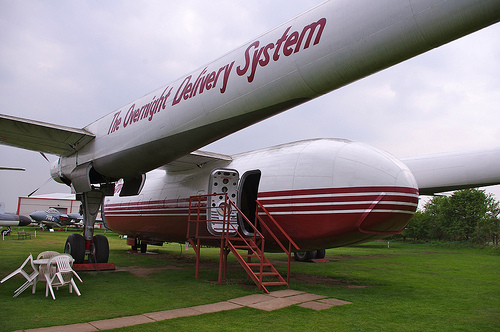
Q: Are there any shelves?
A: No, there are no shelves.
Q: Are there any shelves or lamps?
A: No, there are no shelves or lamps.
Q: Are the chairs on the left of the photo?
A: Yes, the chairs are on the left of the image.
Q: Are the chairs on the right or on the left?
A: The chairs are on the left of the image.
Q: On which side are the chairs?
A: The chairs are on the left of the image.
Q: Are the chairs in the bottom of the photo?
A: Yes, the chairs are in the bottom of the image.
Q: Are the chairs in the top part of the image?
A: No, the chairs are in the bottom of the image.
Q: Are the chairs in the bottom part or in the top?
A: The chairs are in the bottom of the image.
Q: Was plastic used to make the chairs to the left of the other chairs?
A: Yes, the chairs are made of plastic.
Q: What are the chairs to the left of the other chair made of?
A: The chairs are made of plastic.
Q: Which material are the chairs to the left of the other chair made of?
A: The chairs are made of plastic.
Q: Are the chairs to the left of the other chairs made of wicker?
A: No, the chairs are made of plastic.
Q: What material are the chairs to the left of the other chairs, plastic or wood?
A: The chairs are made of plastic.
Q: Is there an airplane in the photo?
A: Yes, there is an airplane.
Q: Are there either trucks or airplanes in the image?
A: Yes, there is an airplane.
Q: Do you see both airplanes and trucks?
A: No, there is an airplane but no trucks.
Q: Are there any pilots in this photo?
A: No, there are no pilots.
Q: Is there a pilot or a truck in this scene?
A: No, there are no pilots or trucks.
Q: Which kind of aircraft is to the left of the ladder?
A: The aircraft is an airplane.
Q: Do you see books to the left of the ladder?
A: No, there is an airplane to the left of the ladder.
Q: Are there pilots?
A: No, there are no pilots.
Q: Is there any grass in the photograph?
A: Yes, there is grass.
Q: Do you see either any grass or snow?
A: Yes, there is grass.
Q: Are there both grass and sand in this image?
A: No, there is grass but no sand.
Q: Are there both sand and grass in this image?
A: No, there is grass but no sand.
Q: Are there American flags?
A: No, there are no American flags.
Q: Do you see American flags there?
A: No, there are no American flags.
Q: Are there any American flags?
A: No, there are no American flags.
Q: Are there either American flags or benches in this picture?
A: No, there are no American flags or benches.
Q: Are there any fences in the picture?
A: No, there are no fences.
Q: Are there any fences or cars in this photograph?
A: No, there are no fences or cars.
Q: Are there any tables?
A: Yes, there is a table.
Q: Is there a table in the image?
A: Yes, there is a table.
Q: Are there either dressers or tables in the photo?
A: Yes, there is a table.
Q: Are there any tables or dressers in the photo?
A: Yes, there is a table.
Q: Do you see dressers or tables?
A: Yes, there is a table.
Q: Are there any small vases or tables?
A: Yes, there is a small table.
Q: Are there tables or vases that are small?
A: Yes, the table is small.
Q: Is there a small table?
A: Yes, there is a small table.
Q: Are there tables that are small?
A: Yes, there is a table that is small.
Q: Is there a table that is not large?
A: Yes, there is a small table.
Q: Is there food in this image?
A: No, there is no food.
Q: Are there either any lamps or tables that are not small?
A: No, there is a table but it is small.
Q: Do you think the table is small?
A: Yes, the table is small.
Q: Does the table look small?
A: Yes, the table is small.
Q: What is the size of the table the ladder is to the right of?
A: The table is small.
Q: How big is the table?
A: The table is small.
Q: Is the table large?
A: No, the table is small.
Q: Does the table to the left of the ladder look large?
A: No, the table is small.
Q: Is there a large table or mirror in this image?
A: No, there is a table but it is small.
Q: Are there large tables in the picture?
A: No, there is a table but it is small.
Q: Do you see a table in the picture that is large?
A: No, there is a table but it is small.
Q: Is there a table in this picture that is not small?
A: No, there is a table but it is small.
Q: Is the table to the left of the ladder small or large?
A: The table is small.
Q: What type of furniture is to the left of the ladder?
A: The piece of furniture is a table.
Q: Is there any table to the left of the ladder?
A: Yes, there is a table to the left of the ladder.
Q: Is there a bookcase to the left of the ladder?
A: No, there is a table to the left of the ladder.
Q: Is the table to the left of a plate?
A: No, the table is to the left of the ladder.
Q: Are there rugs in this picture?
A: No, there are no rugs.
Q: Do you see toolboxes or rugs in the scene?
A: No, there are no rugs or toolboxes.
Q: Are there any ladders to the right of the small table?
A: Yes, there is a ladder to the right of the table.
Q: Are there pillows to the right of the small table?
A: No, there is a ladder to the right of the table.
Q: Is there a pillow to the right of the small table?
A: No, there is a ladder to the right of the table.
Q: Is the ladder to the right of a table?
A: Yes, the ladder is to the right of a table.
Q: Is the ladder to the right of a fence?
A: No, the ladder is to the right of a table.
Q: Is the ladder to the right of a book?
A: No, the ladder is to the right of an airplane.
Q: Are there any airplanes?
A: Yes, there is an airplane.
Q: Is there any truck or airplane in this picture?
A: Yes, there is an airplane.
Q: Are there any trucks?
A: No, there are no trucks.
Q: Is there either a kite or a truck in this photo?
A: No, there are no trucks or kites.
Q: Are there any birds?
A: No, there are no birds.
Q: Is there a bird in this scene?
A: No, there are no birds.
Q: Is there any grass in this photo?
A: Yes, there is grass.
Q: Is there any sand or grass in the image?
A: Yes, there is grass.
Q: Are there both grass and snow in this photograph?
A: No, there is grass but no snow.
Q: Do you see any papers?
A: No, there are no papers.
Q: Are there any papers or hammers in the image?
A: No, there are no papers or hammers.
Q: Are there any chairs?
A: Yes, there is a chair.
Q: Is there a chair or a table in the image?
A: Yes, there is a chair.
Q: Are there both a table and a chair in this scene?
A: Yes, there are both a chair and a table.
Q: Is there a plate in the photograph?
A: No, there are no plates.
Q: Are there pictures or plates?
A: No, there are no plates or pictures.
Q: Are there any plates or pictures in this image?
A: No, there are no plates or pictures.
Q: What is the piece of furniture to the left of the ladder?
A: The piece of furniture is a chair.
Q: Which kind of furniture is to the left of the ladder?
A: The piece of furniture is a chair.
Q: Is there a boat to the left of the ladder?
A: No, there is a chair to the left of the ladder.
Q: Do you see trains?
A: No, there are no trains.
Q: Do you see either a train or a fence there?
A: No, there are no trains or fences.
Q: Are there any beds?
A: No, there are no beds.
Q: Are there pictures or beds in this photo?
A: No, there are no beds or pictures.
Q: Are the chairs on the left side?
A: Yes, the chairs are on the left of the image.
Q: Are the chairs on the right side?
A: No, the chairs are on the left of the image.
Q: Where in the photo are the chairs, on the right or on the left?
A: The chairs are on the left of the image.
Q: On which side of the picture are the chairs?
A: The chairs are on the left of the image.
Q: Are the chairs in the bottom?
A: Yes, the chairs are in the bottom of the image.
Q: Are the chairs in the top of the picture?
A: No, the chairs are in the bottom of the image.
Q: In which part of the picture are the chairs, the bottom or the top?
A: The chairs are in the bottom of the image.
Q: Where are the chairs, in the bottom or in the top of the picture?
A: The chairs are in the bottom of the image.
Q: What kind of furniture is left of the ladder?
A: The pieces of furniture are chairs.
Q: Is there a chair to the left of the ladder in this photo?
A: Yes, there are chairs to the left of the ladder.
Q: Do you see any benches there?
A: No, there are no benches.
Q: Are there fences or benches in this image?
A: No, there are no benches or fences.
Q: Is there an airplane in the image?
A: Yes, there is an airplane.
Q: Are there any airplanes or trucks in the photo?
A: Yes, there is an airplane.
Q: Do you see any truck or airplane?
A: Yes, there is an airplane.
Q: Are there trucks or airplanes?
A: Yes, there is an airplane.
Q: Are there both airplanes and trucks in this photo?
A: No, there is an airplane but no trucks.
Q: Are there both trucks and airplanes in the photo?
A: No, there is an airplane but no trucks.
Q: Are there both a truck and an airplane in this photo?
A: No, there is an airplane but no trucks.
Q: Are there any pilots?
A: No, there are no pilots.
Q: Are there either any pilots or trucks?
A: No, there are no pilots or trucks.